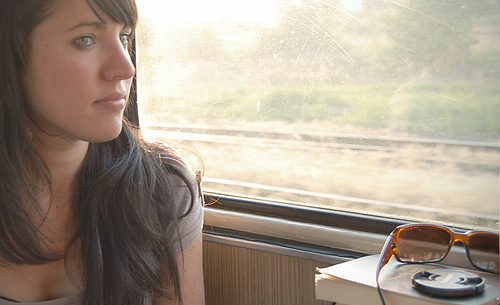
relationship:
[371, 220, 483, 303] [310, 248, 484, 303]
glasses sitting on top of book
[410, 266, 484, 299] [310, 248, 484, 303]
lid on top of book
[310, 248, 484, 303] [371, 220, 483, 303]
book under glasses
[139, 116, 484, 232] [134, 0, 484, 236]
tracks outside of window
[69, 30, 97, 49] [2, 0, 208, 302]
eye of window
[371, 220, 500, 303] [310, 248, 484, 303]
glasses on a book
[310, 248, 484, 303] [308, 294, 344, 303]
book on a shelf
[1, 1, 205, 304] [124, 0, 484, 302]
female sitting on a train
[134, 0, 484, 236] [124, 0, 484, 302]
window of a train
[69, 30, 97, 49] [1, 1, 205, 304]
eye of a female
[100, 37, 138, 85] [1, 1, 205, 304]
nose of a female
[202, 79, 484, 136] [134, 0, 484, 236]
bushes outside window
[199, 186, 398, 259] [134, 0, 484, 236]
bottom of a window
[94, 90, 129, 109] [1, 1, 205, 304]
lips on a female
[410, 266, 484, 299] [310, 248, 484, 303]
lid on a book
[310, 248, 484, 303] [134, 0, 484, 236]
book near a window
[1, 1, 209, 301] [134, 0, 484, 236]
female near a window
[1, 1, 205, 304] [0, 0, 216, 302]
female with hair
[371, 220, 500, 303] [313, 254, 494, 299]
glasses next to book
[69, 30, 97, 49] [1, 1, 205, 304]
eye of female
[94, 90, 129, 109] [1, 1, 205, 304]
lips of female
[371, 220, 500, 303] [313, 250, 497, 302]
glasses on book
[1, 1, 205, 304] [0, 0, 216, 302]
female has hair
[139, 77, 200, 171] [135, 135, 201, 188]
sun on girl`s shoulder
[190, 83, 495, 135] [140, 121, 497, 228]
bushes on side tracks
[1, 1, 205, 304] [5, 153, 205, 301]
female wearing shirt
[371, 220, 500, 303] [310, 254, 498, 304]
glasses on top book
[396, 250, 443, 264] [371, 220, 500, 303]
light shining on glasses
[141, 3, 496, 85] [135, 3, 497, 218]
trees outside window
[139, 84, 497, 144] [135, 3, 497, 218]
bushes outside window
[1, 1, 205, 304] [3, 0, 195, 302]
female has hair